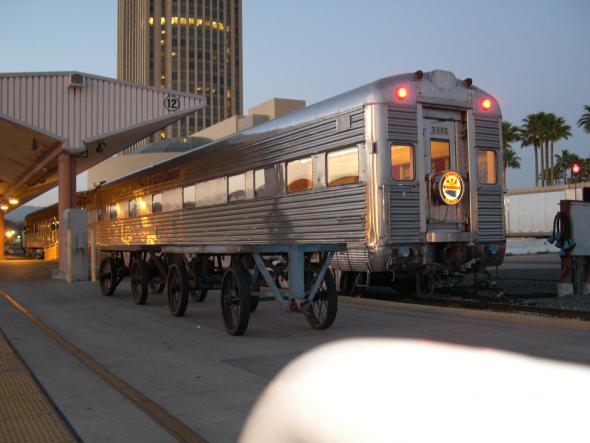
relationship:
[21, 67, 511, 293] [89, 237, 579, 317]
train on tracks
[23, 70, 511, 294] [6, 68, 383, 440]
train in station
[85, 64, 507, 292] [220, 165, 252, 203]
train has window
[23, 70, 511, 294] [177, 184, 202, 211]
train has window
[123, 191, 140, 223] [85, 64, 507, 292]
window on train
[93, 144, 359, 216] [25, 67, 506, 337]
window on train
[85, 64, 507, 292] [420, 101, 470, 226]
train has door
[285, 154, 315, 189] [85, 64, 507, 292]
window of train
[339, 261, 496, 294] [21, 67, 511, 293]
wheels of train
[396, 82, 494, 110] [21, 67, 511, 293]
lights on train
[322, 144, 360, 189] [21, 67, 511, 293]
window on side of train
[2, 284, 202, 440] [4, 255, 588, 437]
line on ground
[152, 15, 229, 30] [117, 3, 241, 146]
lights in building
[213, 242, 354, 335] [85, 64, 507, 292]
wheels on train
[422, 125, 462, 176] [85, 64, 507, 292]
window on train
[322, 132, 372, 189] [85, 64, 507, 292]
window on train